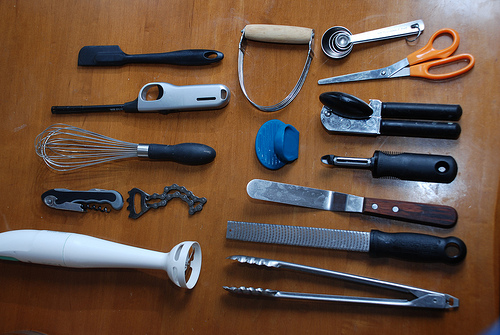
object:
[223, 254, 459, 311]
tong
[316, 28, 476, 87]
scissor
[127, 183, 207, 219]
bottle opener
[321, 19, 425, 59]
spoon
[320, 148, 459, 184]
peeler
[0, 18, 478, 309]
tools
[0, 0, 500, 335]
kitchen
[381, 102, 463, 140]
handle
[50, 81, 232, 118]
lighter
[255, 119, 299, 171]
spatual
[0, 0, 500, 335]
table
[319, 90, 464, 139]
can opener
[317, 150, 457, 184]
knife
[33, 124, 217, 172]
eggbeater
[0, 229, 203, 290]
brush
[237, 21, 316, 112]
server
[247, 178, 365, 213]
blade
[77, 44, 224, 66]
cork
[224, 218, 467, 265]
scraper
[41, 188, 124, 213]
whisk